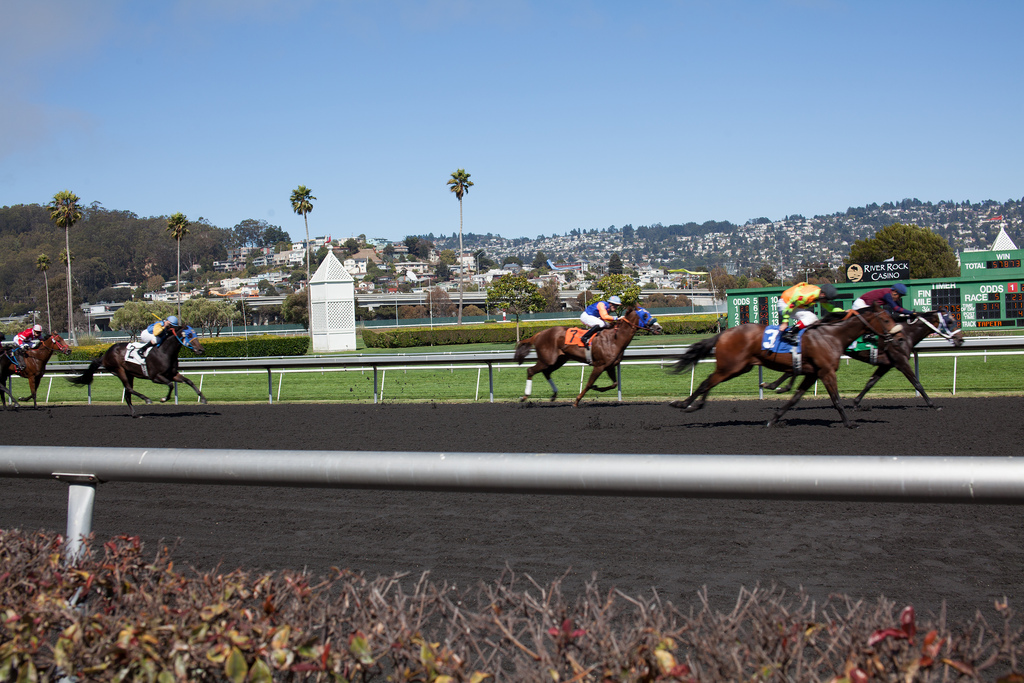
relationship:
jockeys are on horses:
[7, 271, 859, 365] [13, 291, 958, 402]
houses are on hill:
[266, 204, 1010, 338] [0, 196, 1010, 320]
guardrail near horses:
[13, 338, 1020, 408] [6, 300, 951, 419]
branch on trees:
[48, 187, 81, 246] [33, 178, 96, 367]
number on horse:
[750, 341, 817, 380] [670, 291, 908, 410]